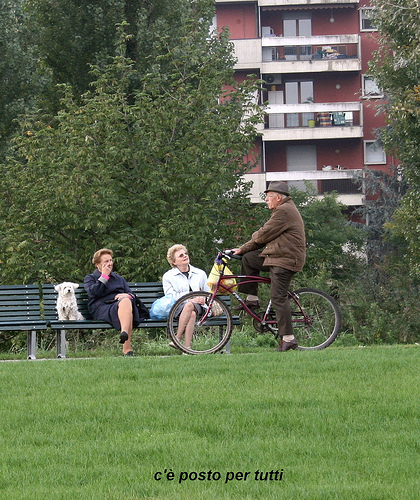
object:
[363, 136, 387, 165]
window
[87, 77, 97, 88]
leaves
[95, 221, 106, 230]
leaves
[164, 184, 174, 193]
leaves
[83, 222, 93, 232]
leaves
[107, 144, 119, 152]
leaves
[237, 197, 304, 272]
jacket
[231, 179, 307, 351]
man